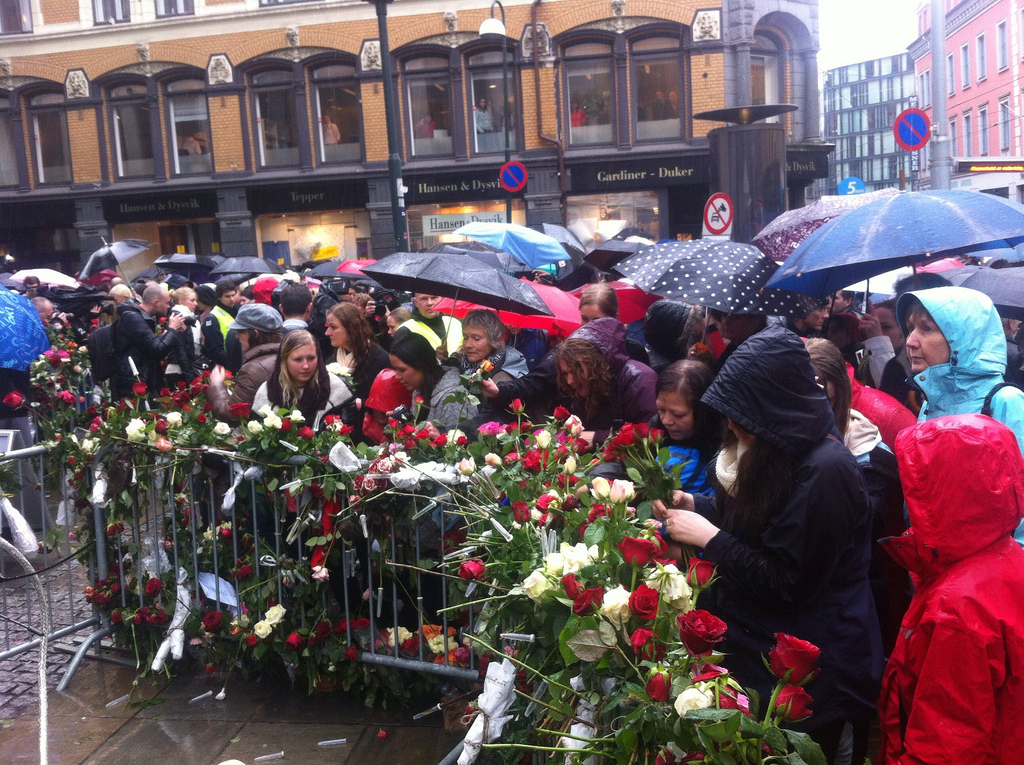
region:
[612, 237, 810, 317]
black umbrella with white polka dots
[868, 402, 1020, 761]
person wearing a red coat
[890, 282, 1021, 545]
woman wearing hooded light blue coat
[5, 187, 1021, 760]
people gathered around white and red roses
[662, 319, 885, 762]
woman in a hooded black coat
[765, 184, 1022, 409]
person holding a blue umbrella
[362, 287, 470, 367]
man wearing bright yellow vest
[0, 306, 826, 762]
long row of red and white roses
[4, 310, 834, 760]
roses lining a metal railing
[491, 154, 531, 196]
circular blue and red sign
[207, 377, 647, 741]
Red roses on the fence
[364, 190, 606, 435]
Person holding a blue umbrella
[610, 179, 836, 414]
The umbrella has dots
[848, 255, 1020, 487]
Person wearing a hooded light blue coat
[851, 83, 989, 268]
A red and blue street sign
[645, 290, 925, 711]
The person is wearing a black hooded coat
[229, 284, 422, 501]
The girl has blonde hair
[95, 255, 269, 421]
The man is holding a black camera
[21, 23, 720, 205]
Wall is red color.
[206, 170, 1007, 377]
people are holding umbrella.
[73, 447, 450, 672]
Rail is grey color.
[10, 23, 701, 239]
Windows are black color.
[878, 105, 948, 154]
Signal board is red and blue.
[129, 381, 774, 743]
Flowers are red and white.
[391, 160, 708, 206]
Letters are white color.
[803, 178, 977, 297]
an umbrella that is blue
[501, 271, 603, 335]
an umbrella that is red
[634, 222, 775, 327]
an umbrella that is spotted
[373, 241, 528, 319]
an umbrella that is black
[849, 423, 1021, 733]
a jacket that is red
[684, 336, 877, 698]
a jacket that is black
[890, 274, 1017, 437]
a jacket that is blue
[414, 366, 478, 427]
a jacket that is grey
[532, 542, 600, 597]
a flower that is white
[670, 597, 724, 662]
a flower that is red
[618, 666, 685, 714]
flower on the plant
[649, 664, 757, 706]
flower on the plant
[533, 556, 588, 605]
flower on the plant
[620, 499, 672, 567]
flower on the plant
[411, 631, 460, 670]
flower on the plant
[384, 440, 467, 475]
flower on the plant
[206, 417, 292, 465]
flower on the plant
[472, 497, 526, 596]
flower on the plant